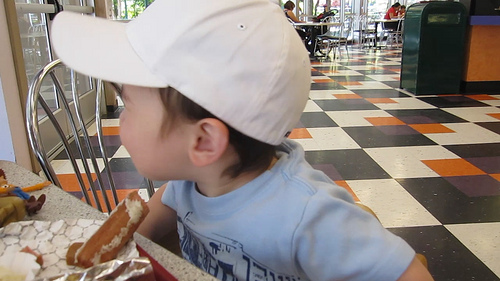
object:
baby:
[311, 4, 339, 23]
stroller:
[305, 9, 339, 57]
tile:
[375, 125, 420, 136]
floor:
[430, 101, 485, 120]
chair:
[25, 58, 155, 216]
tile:
[394, 177, 500, 225]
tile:
[304, 149, 393, 181]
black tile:
[340, 125, 438, 148]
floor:
[357, 175, 380, 208]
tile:
[442, 174, 500, 197]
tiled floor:
[415, 95, 491, 108]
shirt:
[160, 138, 415, 281]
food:
[0, 266, 24, 281]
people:
[384, 2, 400, 20]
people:
[283, 0, 306, 23]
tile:
[324, 110, 406, 128]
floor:
[320, 55, 477, 255]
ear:
[188, 117, 229, 166]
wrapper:
[0, 219, 156, 281]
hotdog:
[75, 189, 151, 269]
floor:
[347, 60, 361, 68]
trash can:
[399, 0, 469, 96]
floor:
[463, 252, 500, 265]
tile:
[408, 123, 457, 134]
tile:
[419, 158, 488, 177]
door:
[0, 0, 108, 174]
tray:
[117, 231, 223, 281]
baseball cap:
[49, 0, 312, 146]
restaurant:
[0, 0, 500, 281]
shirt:
[384, 7, 398, 20]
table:
[373, 19, 404, 50]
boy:
[119, 0, 437, 281]